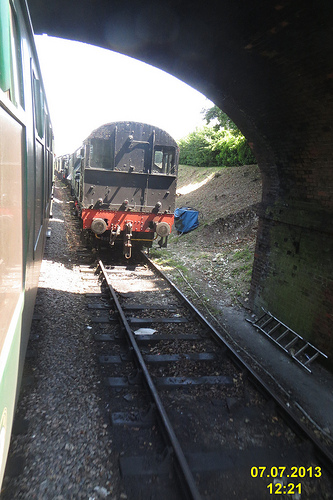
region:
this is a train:
[63, 116, 181, 231]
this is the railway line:
[108, 288, 231, 387]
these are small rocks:
[45, 396, 79, 455]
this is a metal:
[153, 388, 186, 466]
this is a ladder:
[255, 308, 327, 369]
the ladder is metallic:
[261, 310, 305, 362]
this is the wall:
[266, 201, 329, 293]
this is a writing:
[243, 461, 308, 498]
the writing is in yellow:
[250, 459, 303, 499]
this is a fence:
[193, 139, 226, 155]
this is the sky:
[57, 59, 86, 98]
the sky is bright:
[53, 54, 94, 119]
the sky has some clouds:
[62, 64, 113, 114]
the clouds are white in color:
[50, 54, 95, 105]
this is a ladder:
[243, 304, 321, 367]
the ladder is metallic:
[239, 307, 309, 356]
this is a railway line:
[157, 393, 206, 476]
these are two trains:
[3, 117, 179, 306]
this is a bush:
[199, 129, 230, 150]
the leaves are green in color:
[209, 109, 219, 128]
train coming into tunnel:
[61, 115, 179, 246]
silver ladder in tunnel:
[245, 305, 330, 373]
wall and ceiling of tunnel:
[50, 4, 326, 326]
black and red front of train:
[82, 126, 180, 248]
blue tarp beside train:
[176, 204, 197, 235]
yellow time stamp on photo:
[248, 459, 319, 499]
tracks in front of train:
[93, 251, 328, 499]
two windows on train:
[85, 134, 166, 178]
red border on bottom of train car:
[84, 211, 172, 237]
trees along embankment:
[171, 106, 251, 156]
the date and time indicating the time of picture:
[247, 458, 331, 498]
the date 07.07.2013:
[242, 458, 330, 477]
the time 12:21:
[264, 477, 311, 498]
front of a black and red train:
[82, 110, 188, 263]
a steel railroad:
[80, 258, 320, 494]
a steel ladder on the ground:
[241, 301, 326, 377]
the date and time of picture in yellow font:
[241, 457, 331, 498]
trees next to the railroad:
[176, 108, 264, 166]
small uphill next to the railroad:
[179, 159, 264, 241]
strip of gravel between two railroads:
[35, 286, 109, 497]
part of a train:
[108, 188, 142, 224]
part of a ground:
[54, 442, 83, 473]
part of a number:
[249, 469, 256, 481]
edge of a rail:
[173, 441, 199, 474]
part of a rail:
[170, 420, 203, 457]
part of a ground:
[65, 433, 95, 466]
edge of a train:
[167, 443, 183, 475]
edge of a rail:
[174, 452, 188, 482]